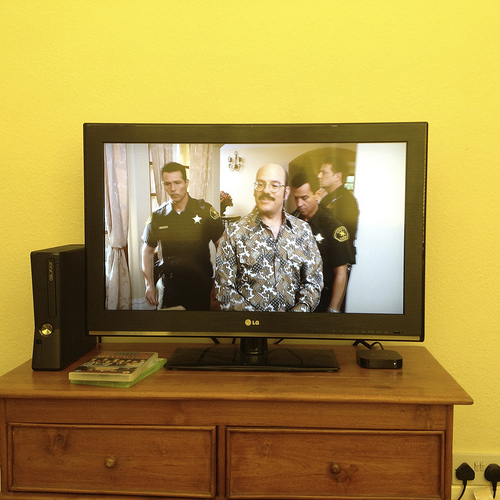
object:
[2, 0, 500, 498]
wall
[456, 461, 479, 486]
plug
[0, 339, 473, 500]
dresser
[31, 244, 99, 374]
xbox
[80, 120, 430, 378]
television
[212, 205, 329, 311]
shirt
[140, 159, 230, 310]
officer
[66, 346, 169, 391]
game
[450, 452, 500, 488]
outlet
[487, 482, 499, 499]
cord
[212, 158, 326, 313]
man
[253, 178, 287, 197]
spectacles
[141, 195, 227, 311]
uniform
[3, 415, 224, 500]
drawer